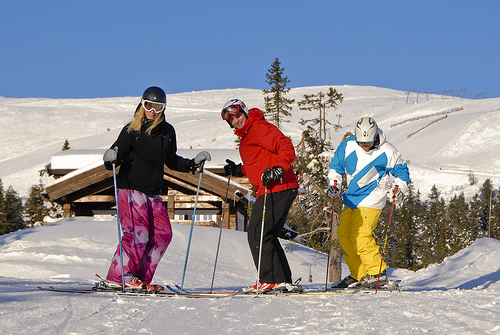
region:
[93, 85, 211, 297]
A woman skier, in black and pink.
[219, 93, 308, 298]
A skier in red and black.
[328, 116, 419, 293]
A skier in blue, white and yellow.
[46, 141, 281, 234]
A ski lodge in the background.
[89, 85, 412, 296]
3 skiers taking a break.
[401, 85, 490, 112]
Ski lifts on a mountain.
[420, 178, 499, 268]
Pine trees in the back.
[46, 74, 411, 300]
Skiers at a ski resort.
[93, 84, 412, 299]
Skiers ready to ski.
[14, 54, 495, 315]
A day on the slopes.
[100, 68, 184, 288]
skier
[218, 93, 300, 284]
skier in red jacket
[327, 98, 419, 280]
female skier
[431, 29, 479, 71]
white clouds in blue sky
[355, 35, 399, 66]
white clouds in blue sky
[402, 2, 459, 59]
white clouds in blue sky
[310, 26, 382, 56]
white clouds in blue sky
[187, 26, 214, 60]
white clouds in blue sky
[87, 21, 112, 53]
white clouds in blue sky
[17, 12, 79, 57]
white clouds in blue sky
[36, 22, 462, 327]
The people are up in the mountains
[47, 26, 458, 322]
The people are doing some snow skiing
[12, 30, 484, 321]
Some people are wearing helmets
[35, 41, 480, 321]
Some people are wearing ski goggles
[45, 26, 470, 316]
Some people are holding ski poles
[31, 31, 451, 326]
Some people are at a ski resort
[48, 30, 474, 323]
Some people are wearing warm clothes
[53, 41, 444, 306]
Some people are wearing ski gloves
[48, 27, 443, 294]
Some people are out in the sunshine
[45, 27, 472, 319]
Some people are enjoying the day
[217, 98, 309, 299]
PERDON STANDING ON SKIS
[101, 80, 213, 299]
PERSON STANDING ON SKIS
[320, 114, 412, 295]
PERSON STANDING ON SKIS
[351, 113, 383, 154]
HEAD OF SKI PERSON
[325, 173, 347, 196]
HAND OF SKI PERSON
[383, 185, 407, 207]
HAND OF SKI PERSON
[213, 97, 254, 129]
HEAD OF SKI PERSON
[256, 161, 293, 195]
HAND OF SKI PERSON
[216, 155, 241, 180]
HAND OF SKI PERSON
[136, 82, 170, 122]
HEAD OF SKI PERSON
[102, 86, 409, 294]
Three people skiing on the hill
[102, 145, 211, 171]
Gloves on the woman on the left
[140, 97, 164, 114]
Googles on the woman on the left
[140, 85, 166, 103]
Helmet on the woman on the left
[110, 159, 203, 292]
Ski poles the woman on the left holding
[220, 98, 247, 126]
Helmet on the woman in the middle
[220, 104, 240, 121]
Googles on the woman in the middle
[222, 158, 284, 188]
Gloves on the woman in the middle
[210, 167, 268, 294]
Ski poles the woman in the middle holding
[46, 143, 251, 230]
Small house on the hill